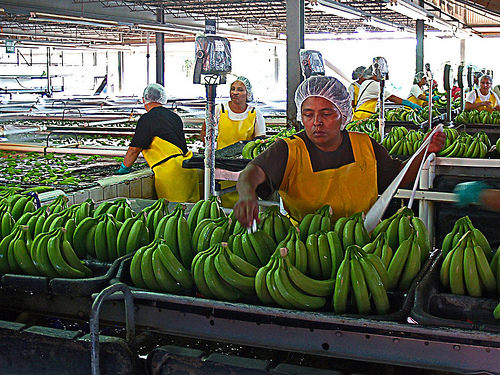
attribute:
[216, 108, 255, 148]
vest — yellow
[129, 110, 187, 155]
shirt — black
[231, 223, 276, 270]
bananas — touched, green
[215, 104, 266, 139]
undershirt — white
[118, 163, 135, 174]
glove — blue, green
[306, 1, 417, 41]
lights — hanging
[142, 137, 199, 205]
apron — yellow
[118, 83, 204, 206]
person — standing, working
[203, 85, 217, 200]
pole — metal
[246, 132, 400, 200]
shirt — brown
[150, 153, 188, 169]
strap — black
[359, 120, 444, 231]
paper — white